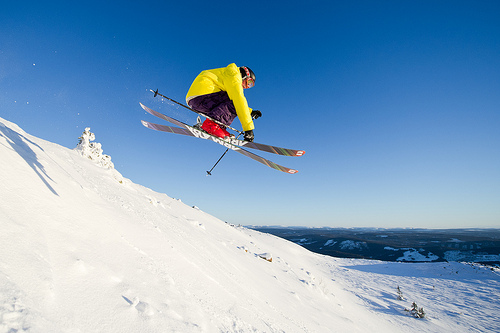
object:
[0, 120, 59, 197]
shadow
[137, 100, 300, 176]
skiis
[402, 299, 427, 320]
tree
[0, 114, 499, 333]
snow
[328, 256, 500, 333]
ground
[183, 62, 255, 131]
jacket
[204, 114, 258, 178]
poles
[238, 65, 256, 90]
goggles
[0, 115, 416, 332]
slope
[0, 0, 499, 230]
sky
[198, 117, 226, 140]
shoes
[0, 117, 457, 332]
hill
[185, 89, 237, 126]
pants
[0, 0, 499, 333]
landscape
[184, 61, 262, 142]
man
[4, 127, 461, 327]
snow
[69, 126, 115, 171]
tree